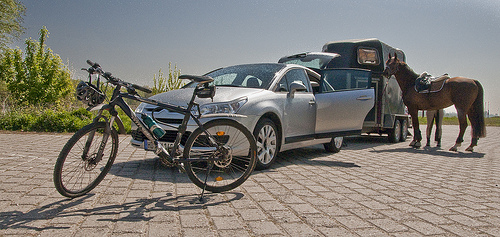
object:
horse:
[380, 51, 487, 154]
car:
[129, 61, 375, 170]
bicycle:
[52, 58, 260, 196]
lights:
[208, 130, 231, 193]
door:
[311, 64, 376, 140]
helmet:
[74, 80, 105, 108]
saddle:
[415, 70, 451, 94]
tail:
[468, 78, 488, 139]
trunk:
[277, 52, 342, 71]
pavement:
[264, 157, 496, 230]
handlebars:
[80, 60, 153, 95]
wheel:
[183, 118, 258, 193]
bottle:
[138, 112, 167, 139]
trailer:
[278, 38, 409, 143]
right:
[380, 51, 489, 152]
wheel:
[248, 119, 281, 171]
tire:
[50, 121, 120, 197]